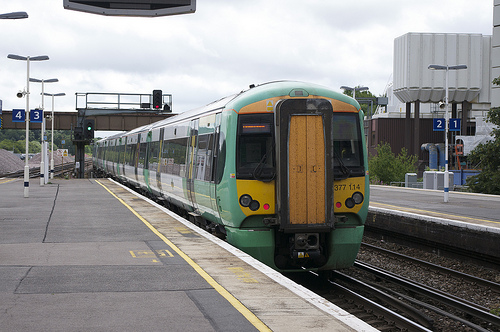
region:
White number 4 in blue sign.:
[5, 100, 44, 151]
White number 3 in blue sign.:
[26, 110, 43, 117]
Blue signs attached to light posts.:
[16, 85, 76, 159]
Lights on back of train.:
[231, 175, 419, 263]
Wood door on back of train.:
[280, 112, 352, 239]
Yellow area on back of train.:
[231, 106, 387, 276]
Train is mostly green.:
[117, 127, 326, 264]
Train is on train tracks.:
[318, 250, 488, 327]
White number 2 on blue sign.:
[422, 112, 458, 159]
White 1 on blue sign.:
[446, 110, 469, 150]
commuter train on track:
[127, 76, 384, 277]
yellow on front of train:
[226, 172, 291, 227]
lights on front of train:
[235, 191, 281, 218]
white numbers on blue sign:
[7, 103, 53, 129]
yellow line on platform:
[156, 235, 233, 308]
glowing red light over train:
[146, 87, 178, 131]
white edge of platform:
[269, 272, 336, 320]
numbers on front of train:
[325, 177, 363, 199]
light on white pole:
[422, 58, 467, 175]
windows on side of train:
[104, 134, 197, 176]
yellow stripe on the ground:
[181, 253, 206, 263]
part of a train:
[326, 230, 344, 250]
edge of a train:
[225, 103, 247, 150]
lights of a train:
[235, 192, 255, 209]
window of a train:
[251, 126, 261, 154]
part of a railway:
[360, 298, 375, 306]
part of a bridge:
[122, 114, 132, 118]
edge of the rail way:
[403, 198, 432, 243]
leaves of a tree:
[478, 165, 485, 174]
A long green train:
[68, 76, 388, 278]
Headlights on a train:
[234, 187, 363, 214]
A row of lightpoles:
[0, 6, 68, 201]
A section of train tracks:
[288, 219, 498, 328]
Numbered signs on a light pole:
[427, 112, 464, 136]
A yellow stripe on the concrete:
[86, 170, 278, 330]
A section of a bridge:
[1, 98, 201, 150]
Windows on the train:
[82, 135, 227, 191]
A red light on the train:
[260, 199, 273, 214]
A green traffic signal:
[74, 113, 97, 147]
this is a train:
[156, 85, 348, 222]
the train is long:
[146, 83, 297, 206]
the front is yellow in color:
[292, 124, 322, 204]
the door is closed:
[180, 122, 202, 199]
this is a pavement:
[32, 192, 120, 324]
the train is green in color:
[199, 188, 232, 217]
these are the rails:
[375, 270, 482, 330]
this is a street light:
[426, 61, 471, 75]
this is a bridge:
[108, 112, 133, 131]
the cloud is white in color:
[211, 19, 276, 54]